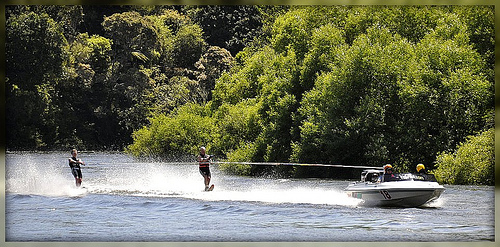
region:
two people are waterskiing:
[48, 125, 230, 207]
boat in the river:
[336, 155, 453, 205]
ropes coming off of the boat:
[209, 150, 361, 173]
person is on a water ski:
[194, 137, 216, 195]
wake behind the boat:
[239, 185, 332, 206]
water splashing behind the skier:
[21, 145, 62, 197]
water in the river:
[37, 205, 216, 227]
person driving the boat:
[381, 161, 390, 176]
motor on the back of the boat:
[360, 170, 374, 181]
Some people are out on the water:
[18, 27, 478, 234]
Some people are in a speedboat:
[26, 28, 471, 229]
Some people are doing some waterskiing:
[16, 50, 476, 216]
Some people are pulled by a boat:
[37, 51, 463, 228]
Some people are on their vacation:
[35, 76, 485, 228]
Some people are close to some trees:
[16, 41, 471, 232]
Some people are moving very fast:
[30, 55, 465, 230]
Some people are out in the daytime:
[22, 33, 492, 208]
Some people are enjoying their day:
[24, 49, 471, 232]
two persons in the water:
[38, 123, 255, 220]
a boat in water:
[329, 127, 482, 224]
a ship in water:
[335, 81, 474, 231]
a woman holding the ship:
[183, 115, 244, 228]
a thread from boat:
[232, 136, 355, 203]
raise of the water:
[33, 147, 309, 221]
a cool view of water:
[64, 198, 236, 245]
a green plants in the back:
[186, 11, 478, 133]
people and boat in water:
[46, 109, 476, 229]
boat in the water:
[336, 157, 446, 212]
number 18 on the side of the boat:
[378, 188, 395, 200]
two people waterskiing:
[64, 145, 219, 197]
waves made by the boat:
[225, 182, 363, 209]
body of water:
[4, 146, 495, 241]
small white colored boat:
[346, 178, 446, 210]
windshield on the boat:
[379, 169, 448, 185]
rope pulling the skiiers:
[85, 158, 390, 173]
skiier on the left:
[67, 144, 90, 196]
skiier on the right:
[194, 141, 219, 194]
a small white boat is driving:
[334, 155, 431, 209]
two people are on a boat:
[380, 158, 438, 183]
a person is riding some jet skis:
[192, 141, 224, 193]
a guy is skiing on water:
[50, 152, 102, 184]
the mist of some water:
[94, 159, 129, 190]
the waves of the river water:
[194, 206, 245, 234]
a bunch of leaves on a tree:
[248, 49, 326, 130]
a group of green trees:
[52, 31, 173, 105]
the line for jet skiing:
[272, 143, 312, 183]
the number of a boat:
[368, 183, 400, 203]